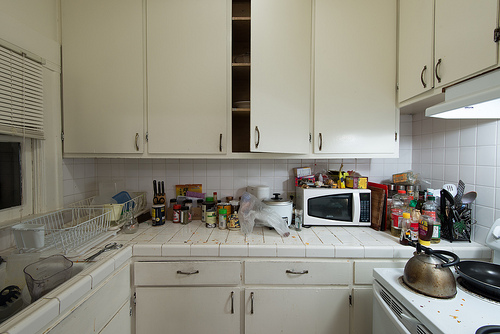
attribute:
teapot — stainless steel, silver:
[402, 241, 460, 300]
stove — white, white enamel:
[369, 225, 500, 333]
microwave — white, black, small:
[296, 186, 374, 227]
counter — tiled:
[136, 206, 486, 259]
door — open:
[246, 0, 315, 156]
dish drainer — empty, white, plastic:
[9, 205, 117, 259]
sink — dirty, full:
[0, 238, 87, 330]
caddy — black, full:
[446, 207, 474, 241]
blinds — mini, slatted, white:
[0, 36, 46, 140]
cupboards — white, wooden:
[63, 5, 398, 161]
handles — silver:
[253, 125, 262, 150]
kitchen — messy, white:
[5, 152, 473, 231]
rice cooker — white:
[261, 192, 294, 230]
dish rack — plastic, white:
[66, 190, 150, 230]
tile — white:
[126, 226, 399, 256]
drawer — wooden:
[132, 258, 377, 287]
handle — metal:
[177, 268, 201, 279]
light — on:
[425, 72, 499, 120]